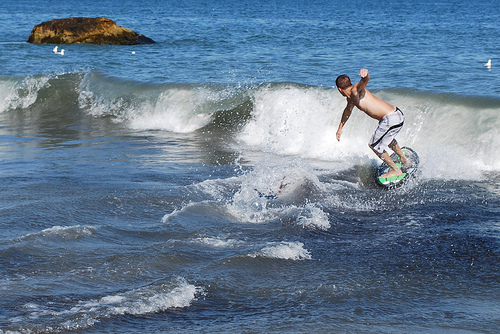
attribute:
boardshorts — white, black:
[366, 105, 404, 154]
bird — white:
[481, 55, 496, 69]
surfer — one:
[330, 69, 420, 186]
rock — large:
[14, 11, 152, 51]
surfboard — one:
[379, 145, 414, 182]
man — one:
[328, 57, 415, 177]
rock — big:
[30, 11, 140, 51]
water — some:
[52, 41, 297, 233]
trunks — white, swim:
[373, 112, 403, 155]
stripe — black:
[366, 117, 411, 152]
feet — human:
[374, 156, 411, 179]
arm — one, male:
[354, 58, 374, 98]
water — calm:
[207, 19, 357, 68]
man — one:
[330, 62, 419, 184]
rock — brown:
[24, 13, 152, 45]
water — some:
[30, 46, 177, 85]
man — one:
[330, 65, 407, 176]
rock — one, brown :
[21, 10, 146, 43]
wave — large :
[19, 79, 338, 137]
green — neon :
[381, 170, 405, 183]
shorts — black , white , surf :
[360, 109, 404, 148]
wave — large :
[242, 85, 332, 153]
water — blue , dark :
[210, 38, 315, 77]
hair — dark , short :
[335, 73, 356, 90]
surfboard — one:
[373, 142, 423, 187]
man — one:
[324, 62, 412, 172]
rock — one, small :
[28, 19, 153, 49]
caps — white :
[163, 153, 340, 272]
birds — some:
[30, 40, 499, 76]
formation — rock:
[32, 14, 158, 54]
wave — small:
[15, 70, 498, 202]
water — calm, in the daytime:
[151, 7, 493, 83]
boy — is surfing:
[322, 65, 419, 185]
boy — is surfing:
[322, 63, 410, 177]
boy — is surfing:
[330, 63, 417, 174]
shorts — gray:
[372, 110, 410, 158]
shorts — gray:
[365, 109, 406, 167]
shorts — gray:
[366, 105, 407, 157]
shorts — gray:
[371, 107, 402, 164]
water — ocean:
[1, 40, 497, 327]